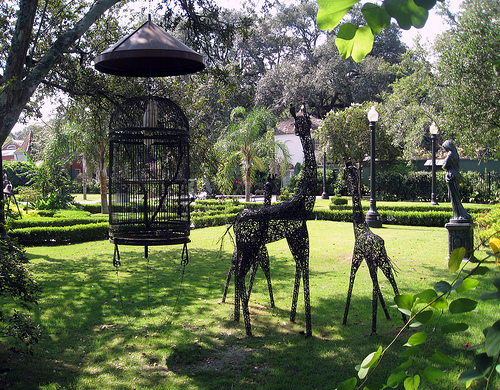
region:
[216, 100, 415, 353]
Two black metal wire giraffes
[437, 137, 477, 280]
Gray statue of woman in a dress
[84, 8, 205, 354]
Large black metal hanging bird cage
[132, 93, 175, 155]
White bird inside of birdcage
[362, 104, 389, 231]
Tall black outdoor light with white bulb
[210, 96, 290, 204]
Medium sized tropical tree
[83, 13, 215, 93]
Black metal hood above birdcage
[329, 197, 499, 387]
Deep green leaves on thin branches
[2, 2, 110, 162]
Thick gray branches of tall tree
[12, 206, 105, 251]
Low to the ground green garden shrubbery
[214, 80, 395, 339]
two statues of giraffes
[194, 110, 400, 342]
three statues of giraffes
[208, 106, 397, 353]
black metal statues of giraffes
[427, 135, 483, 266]
statues on base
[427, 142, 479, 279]
statue of woman on a lawn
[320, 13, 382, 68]
green leaf of tree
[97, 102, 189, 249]
metal bird cage hanging down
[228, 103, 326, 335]
large metal statue of giraffe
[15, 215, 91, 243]
cut hedges on side of field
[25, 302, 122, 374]
shadows on ground from tree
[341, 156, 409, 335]
small giraffe statue on top of grass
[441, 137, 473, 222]
statue on top of a pedestal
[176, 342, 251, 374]
bare patch worn into grass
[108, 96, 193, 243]
metal birdcage is hanging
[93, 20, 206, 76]
canopy over bird cage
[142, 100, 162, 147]
white bird inside bird cage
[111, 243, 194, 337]
chains hanging under bird cage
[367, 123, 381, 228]
black metal lamp post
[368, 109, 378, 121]
white lamp on top of lamp post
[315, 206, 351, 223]
green hedge behind lamp post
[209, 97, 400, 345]
black wire scuptures of giraffes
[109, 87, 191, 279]
a black cage with a cockatoo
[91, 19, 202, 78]
a guard to prevent squirrels getting to the cage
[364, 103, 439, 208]
glass globed street lights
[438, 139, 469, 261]
statue on a pedestal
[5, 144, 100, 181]
buildings painted red with white trim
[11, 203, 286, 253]
low hedges around each area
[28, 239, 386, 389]
shade from the trees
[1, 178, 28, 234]
a bell hang in the next area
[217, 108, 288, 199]
a short palm tree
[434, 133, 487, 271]
A statue is in a courtyard.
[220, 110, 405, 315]
Animal art is in a courtyard.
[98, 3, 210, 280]
A birdcage is hanging from a tree.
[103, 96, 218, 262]
A bird is in a birdcage.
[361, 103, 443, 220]
Street lamps is in a courtyard.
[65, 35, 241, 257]
A tree is supporting a birdcage.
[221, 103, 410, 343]
Iron giraffes are in a courtyard.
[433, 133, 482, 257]
A courtyard has a statue.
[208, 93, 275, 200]
A palm tree is in a courtyard.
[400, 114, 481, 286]
A statue is standing in the sunlight.